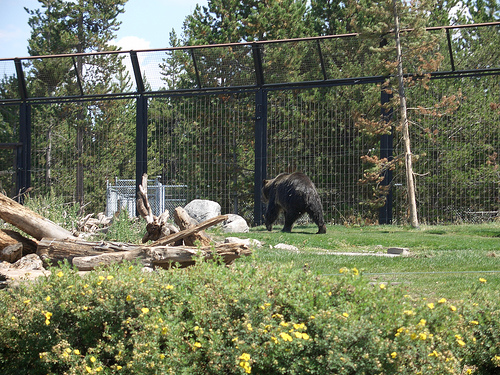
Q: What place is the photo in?
A: It is at the zoo.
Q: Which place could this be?
A: It is a zoo.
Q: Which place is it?
A: It is a zoo.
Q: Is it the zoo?
A: Yes, it is the zoo.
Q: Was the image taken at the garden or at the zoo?
A: It was taken at the zoo.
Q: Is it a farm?
A: No, it is a zoo.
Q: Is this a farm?
A: No, it is a zoo.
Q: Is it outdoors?
A: Yes, it is outdoors.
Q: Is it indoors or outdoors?
A: It is outdoors.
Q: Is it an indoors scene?
A: No, it is outdoors.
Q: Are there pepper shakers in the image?
A: No, there are no pepper shakers.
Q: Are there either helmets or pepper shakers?
A: No, there are no pepper shakers or helmets.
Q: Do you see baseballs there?
A: No, there are no baseballs.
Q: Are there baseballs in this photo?
A: No, there are no baseballs.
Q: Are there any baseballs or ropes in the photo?
A: No, there are no baseballs or ropes.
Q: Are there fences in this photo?
A: Yes, there is a fence.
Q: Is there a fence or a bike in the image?
A: Yes, there is a fence.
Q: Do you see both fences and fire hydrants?
A: No, there is a fence but no fire hydrants.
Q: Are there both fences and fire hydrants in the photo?
A: No, there is a fence but no fire hydrants.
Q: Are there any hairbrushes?
A: No, there are no hairbrushes.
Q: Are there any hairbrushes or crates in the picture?
A: No, there are no hairbrushes or crates.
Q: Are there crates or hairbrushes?
A: No, there are no hairbrushes or crates.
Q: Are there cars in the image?
A: No, there are no cars.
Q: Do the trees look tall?
A: Yes, the trees are tall.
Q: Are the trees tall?
A: Yes, the trees are tall.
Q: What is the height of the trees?
A: The trees are tall.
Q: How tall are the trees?
A: The trees are tall.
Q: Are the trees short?
A: No, the trees are tall.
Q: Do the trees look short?
A: No, the trees are tall.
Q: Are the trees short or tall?
A: The trees are tall.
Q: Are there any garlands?
A: No, there are no garlands.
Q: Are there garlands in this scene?
A: No, there are no garlands.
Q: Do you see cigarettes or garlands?
A: No, there are no garlands or cigarettes.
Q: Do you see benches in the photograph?
A: No, there are no benches.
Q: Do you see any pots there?
A: No, there are no pots.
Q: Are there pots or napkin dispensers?
A: No, there are no pots or napkin dispensers.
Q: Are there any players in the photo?
A: No, there are no players.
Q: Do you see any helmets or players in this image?
A: No, there are no players or helmets.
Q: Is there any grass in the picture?
A: Yes, there is grass.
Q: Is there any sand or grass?
A: Yes, there is grass.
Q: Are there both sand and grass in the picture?
A: No, there is grass but no sand.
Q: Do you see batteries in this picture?
A: No, there are no batteries.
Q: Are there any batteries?
A: No, there are no batteries.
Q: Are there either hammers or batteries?
A: No, there are no batteries or hammers.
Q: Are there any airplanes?
A: No, there are no airplanes.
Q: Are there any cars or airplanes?
A: No, there are no airplanes or cars.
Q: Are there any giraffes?
A: No, there are no giraffes.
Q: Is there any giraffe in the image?
A: No, there are no giraffes.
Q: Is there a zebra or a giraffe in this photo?
A: No, there are no giraffes or zebras.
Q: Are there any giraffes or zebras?
A: No, there are no giraffes or zebras.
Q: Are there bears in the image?
A: Yes, there is a bear.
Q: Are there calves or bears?
A: Yes, there is a bear.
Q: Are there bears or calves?
A: Yes, there is a bear.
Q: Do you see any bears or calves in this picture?
A: Yes, there is a bear.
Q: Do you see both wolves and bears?
A: No, there is a bear but no wolves.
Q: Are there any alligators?
A: No, there are no alligators.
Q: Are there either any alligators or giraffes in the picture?
A: No, there are no alligators or giraffes.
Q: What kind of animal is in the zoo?
A: The animal is a bear.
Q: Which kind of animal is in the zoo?
A: The animal is a bear.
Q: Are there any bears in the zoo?
A: Yes, there is a bear in the zoo.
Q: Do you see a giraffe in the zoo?
A: No, there is a bear in the zoo.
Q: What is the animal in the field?
A: The animal is a bear.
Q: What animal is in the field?
A: The animal is a bear.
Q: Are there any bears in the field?
A: Yes, there is a bear in the field.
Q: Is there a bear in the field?
A: Yes, there is a bear in the field.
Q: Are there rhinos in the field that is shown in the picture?
A: No, there is a bear in the field.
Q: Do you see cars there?
A: No, there are no cars.